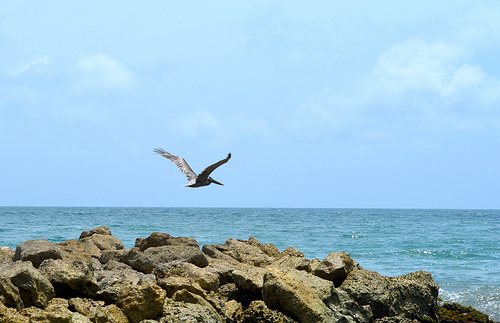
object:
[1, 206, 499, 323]
ocean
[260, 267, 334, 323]
rocks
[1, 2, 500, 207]
sky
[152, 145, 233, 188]
pelican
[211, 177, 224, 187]
beak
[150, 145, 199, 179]
wingspan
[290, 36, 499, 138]
clouds